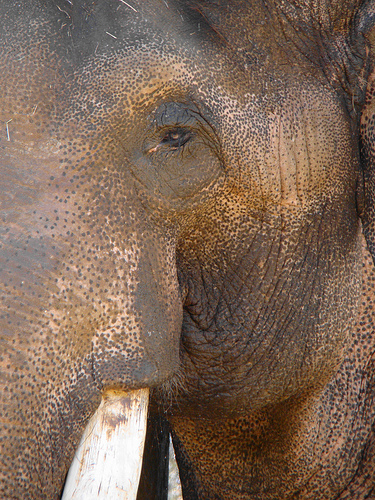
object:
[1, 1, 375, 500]
elephant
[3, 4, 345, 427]
face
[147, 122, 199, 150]
eye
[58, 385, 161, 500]
tusk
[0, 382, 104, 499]
trunk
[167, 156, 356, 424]
wrinkles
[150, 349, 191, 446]
hair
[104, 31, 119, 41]
piece of straw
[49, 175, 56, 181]
spot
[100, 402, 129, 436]
spot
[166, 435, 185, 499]
ground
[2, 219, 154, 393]
discoloration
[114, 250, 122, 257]
spot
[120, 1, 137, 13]
piece of straw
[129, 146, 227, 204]
bags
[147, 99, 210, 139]
lid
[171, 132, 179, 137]
pupil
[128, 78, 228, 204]
wrinkles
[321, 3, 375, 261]
ear